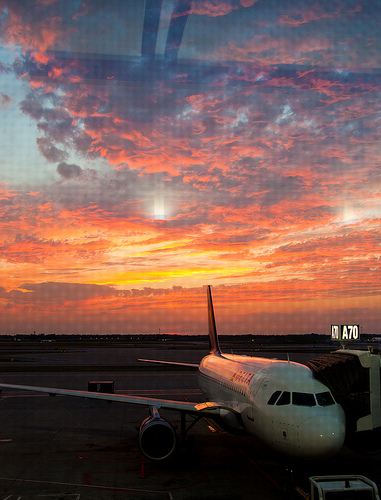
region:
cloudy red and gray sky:
[29, 93, 326, 261]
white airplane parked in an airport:
[4, 279, 379, 477]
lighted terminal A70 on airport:
[340, 318, 362, 344]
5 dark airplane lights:
[264, 381, 347, 418]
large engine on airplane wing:
[125, 394, 185, 473]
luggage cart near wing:
[82, 373, 122, 407]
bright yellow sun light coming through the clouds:
[92, 245, 204, 316]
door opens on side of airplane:
[191, 399, 266, 451]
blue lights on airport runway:
[17, 339, 107, 370]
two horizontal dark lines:
[108, 5, 211, 90]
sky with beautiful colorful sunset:
[48, 167, 246, 284]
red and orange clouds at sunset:
[32, 201, 159, 322]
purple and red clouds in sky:
[39, 160, 169, 261]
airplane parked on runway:
[21, 320, 352, 475]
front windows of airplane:
[252, 380, 353, 457]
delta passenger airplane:
[109, 330, 363, 468]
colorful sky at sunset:
[4, 156, 346, 313]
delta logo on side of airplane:
[220, 354, 272, 394]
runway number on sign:
[318, 312, 365, 352]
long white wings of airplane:
[14, 334, 275, 455]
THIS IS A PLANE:
[0, 278, 357, 467]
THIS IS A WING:
[0, 375, 244, 462]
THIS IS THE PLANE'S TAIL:
[126, 282, 226, 385]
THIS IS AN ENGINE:
[131, 402, 182, 462]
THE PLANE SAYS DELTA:
[231, 362, 258, 394]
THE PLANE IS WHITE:
[3, 282, 349, 475]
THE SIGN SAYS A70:
[325, 318, 363, 348]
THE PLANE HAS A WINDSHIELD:
[266, 387, 346, 417]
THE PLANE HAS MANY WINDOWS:
[195, 362, 249, 399]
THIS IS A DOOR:
[243, 365, 269, 422]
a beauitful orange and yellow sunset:
[0, 1, 378, 333]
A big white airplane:
[1, 277, 368, 475]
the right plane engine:
[133, 409, 181, 461]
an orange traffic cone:
[136, 456, 147, 480]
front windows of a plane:
[270, 386, 336, 409]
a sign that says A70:
[339, 325, 359, 339]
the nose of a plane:
[243, 358, 353, 459]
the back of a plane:
[135, 283, 236, 389]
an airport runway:
[0, 322, 361, 402]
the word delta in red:
[225, 364, 259, 391]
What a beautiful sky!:
[28, 6, 377, 332]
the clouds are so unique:
[61, 48, 345, 259]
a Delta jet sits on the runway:
[0, 265, 358, 491]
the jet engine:
[133, 408, 195, 477]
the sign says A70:
[330, 315, 380, 347]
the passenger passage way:
[302, 349, 379, 453]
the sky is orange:
[81, 239, 372, 329]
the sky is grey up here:
[104, 12, 344, 120]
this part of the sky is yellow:
[107, 257, 237, 302]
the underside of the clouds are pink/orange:
[113, 107, 333, 221]